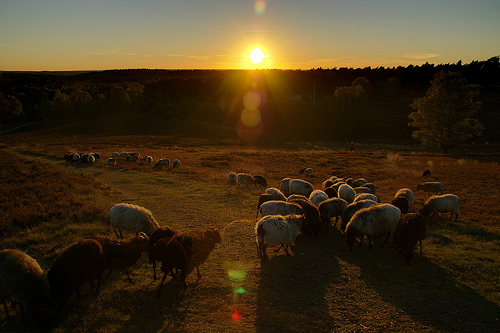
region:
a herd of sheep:
[10, 145, 460, 317]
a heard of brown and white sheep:
[1, 147, 462, 318]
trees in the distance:
[6, 60, 496, 125]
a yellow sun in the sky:
[238, 45, 274, 70]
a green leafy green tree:
[405, 67, 485, 160]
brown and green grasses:
[13, 165, 74, 220]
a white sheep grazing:
[106, 202, 166, 233]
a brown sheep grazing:
[393, 210, 423, 268]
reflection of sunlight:
[228, 71, 275, 159]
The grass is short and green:
[216, 279, 449, 327]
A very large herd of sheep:
[1, 145, 498, 325]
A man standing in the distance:
[342, 132, 367, 161]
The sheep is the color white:
[248, 208, 308, 260]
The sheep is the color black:
[161, 228, 227, 293]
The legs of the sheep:
[143, 267, 210, 293]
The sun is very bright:
[241, 33, 280, 77]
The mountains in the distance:
[11, 57, 497, 120]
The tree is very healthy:
[411, 68, 487, 162]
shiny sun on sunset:
[240, 41, 274, 75]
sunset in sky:
[234, 33, 289, 71]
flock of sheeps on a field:
[0, 135, 460, 317]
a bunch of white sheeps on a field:
[86, 148, 459, 240]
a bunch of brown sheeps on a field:
[8, 142, 428, 330]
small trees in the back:
[4, 65, 484, 153]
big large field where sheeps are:
[0, 122, 496, 327]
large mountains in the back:
[0, 58, 497, 127]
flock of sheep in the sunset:
[0, 141, 479, 318]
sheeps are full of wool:
[0, 147, 465, 330]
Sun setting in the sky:
[246, 44, 266, 69]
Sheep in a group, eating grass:
[251, 172, 459, 264]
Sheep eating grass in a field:
[62, 144, 181, 173]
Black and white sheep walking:
[0, 204, 223, 319]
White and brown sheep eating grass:
[251, 174, 463, 264]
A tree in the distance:
[410, 68, 482, 157]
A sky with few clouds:
[1, 1, 498, 72]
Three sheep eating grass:
[226, 170, 268, 187]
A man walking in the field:
[348, 139, 356, 153]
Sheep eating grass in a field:
[256, 173, 458, 257]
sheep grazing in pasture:
[4, 45, 491, 325]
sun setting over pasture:
[10, 43, 499, 241]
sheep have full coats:
[15, 117, 490, 324]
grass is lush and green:
[19, 118, 483, 318]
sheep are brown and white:
[23, 117, 491, 324]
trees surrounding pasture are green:
[18, 62, 498, 172]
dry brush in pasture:
[373, 142, 498, 186]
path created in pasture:
[16, 143, 475, 324]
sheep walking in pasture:
[18, 173, 235, 325]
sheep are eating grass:
[248, 158, 479, 270]